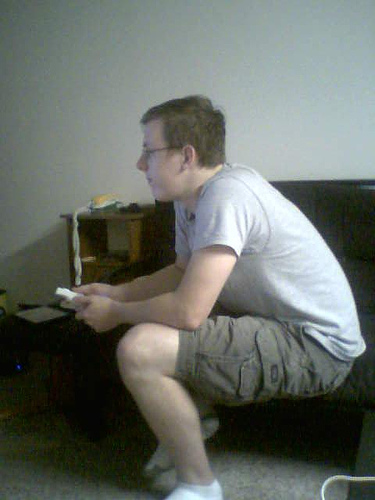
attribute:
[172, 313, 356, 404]
cargo shorts — green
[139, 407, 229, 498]
socks — white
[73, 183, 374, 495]
couch — black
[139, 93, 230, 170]
hair — brown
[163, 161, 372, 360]
shirt — white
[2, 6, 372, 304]
wall — light grey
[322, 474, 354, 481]
cord — white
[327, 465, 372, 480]
piece — cord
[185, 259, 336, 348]
man — wearing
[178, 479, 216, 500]
socks — white, grey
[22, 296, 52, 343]
stand — black , white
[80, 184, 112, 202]
phone — white, yellow, land line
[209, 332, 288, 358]
shorts — green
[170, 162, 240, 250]
man — wearing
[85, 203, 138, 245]
stand — light brown, with shelfs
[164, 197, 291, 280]
man — wearing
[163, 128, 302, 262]
man — sitting down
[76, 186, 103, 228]
telephone — white, corded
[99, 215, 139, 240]
furntiture — piece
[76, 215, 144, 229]
piece — wooden, furntiture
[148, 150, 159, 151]
glasses — pair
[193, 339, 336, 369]
shorts — pair, khaki 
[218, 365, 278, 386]
pair — khaki , shorts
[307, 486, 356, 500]
wire — colored, white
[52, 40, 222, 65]
wall — white, colored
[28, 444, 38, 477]
carpet — tan color, Some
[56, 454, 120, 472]
color — tan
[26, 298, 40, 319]
piece — White, of paper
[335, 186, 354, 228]
futon — colored,  dark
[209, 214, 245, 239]
man —  holding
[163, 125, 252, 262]
man — sitting down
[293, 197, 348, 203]
sofa — black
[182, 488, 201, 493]
socks — white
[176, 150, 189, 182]
man — wearing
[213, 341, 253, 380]
shorts — green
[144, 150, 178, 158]
eyeglasses — pair 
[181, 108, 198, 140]
hair — brown